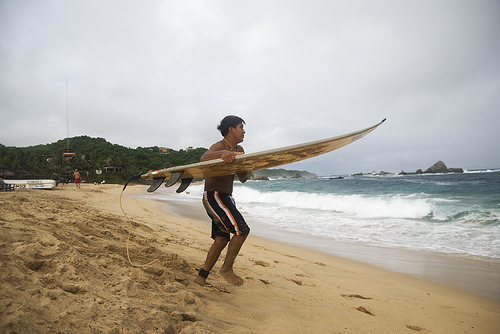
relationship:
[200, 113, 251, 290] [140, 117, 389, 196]
man has surfboard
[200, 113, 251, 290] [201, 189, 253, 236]
man wearing shorts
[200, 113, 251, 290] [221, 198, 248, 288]
man has leg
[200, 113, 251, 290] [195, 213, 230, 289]
man has leg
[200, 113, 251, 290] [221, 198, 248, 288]
boy has foot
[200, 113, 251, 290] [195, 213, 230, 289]
boy has foot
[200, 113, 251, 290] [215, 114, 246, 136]
boy has hair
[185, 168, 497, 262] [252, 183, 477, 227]
water has waves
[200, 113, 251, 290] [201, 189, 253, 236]
man has shorts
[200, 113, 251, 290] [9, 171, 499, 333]
man at beach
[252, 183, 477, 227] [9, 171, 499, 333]
waves crushing on beach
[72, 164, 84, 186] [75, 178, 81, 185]
person has shorts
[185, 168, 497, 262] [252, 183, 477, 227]
sea produces waves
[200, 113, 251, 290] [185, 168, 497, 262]
man going to sea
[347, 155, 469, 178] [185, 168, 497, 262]
rocks in sea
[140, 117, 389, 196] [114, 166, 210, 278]
surfboard has leash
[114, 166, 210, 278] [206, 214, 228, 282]
leash tied to foot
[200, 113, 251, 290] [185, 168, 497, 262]
man going to surf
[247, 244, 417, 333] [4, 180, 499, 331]
footprints in sand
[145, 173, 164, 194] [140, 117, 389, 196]
fin on surfboard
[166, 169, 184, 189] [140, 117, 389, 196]
fin on surfboard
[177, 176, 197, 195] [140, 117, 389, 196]
fin on surfboard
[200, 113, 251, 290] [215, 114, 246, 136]
man has hair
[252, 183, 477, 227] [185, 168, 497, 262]
waves in ocean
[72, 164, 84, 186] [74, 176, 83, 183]
person has shorts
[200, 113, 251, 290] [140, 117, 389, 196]
man carrying surfboard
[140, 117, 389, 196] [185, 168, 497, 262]
surfboard going to water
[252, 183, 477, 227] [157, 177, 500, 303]
waves on shore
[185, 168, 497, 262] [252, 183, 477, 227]
ocean has waves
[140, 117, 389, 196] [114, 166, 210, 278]
surfboard has strap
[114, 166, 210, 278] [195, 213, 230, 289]
strap on ankle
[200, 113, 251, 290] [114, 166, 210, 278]
man has strap